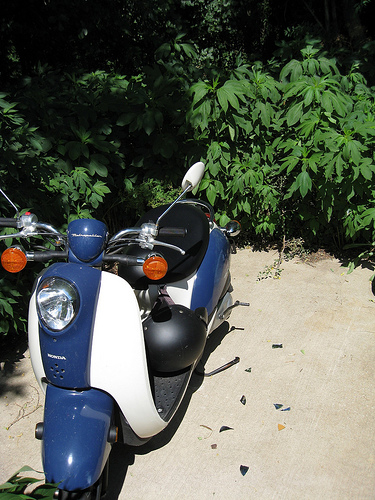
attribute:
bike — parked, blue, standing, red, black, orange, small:
[19, 172, 230, 456]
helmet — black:
[142, 305, 213, 367]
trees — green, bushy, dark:
[265, 45, 356, 146]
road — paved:
[258, 306, 340, 436]